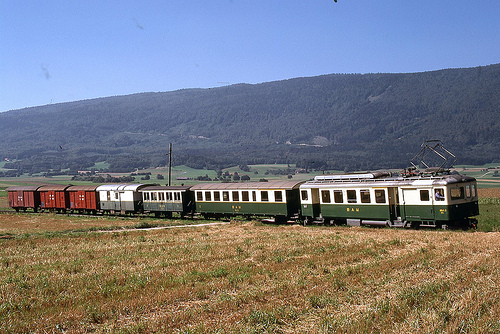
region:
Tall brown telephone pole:
[159, 140, 182, 185]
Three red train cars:
[10, 180, 101, 214]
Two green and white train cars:
[185, 176, 469, 232]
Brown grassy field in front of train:
[22, 217, 477, 332]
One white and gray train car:
[95, 182, 142, 217]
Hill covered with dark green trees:
[6, 60, 489, 172]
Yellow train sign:
[339, 207, 364, 212]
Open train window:
[443, 185, 466, 200]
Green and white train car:
[139, 185, 186, 215]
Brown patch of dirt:
[73, 162, 151, 179]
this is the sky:
[3, 6, 485, 59]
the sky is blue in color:
[3, 0, 188, 38]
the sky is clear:
[11, 6, 483, 29]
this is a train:
[8, 178, 483, 219]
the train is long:
[11, 177, 481, 217]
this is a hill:
[140, 67, 499, 139]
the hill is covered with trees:
[196, 105, 316, 142]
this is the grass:
[52, 245, 218, 326]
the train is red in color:
[18, 190, 75, 201]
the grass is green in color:
[481, 203, 495, 229]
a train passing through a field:
[6, 177, 478, 235]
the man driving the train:
[433, 188, 444, 200]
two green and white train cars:
[188, 170, 480, 232]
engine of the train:
[298, 167, 482, 233]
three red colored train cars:
[7, 180, 97, 214]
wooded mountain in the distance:
[0, 60, 496, 165]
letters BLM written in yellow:
[341, 202, 363, 212]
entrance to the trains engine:
[386, 183, 404, 228]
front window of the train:
[446, 182, 476, 202]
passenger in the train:
[222, 192, 227, 199]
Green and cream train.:
[286, 176, 495, 231]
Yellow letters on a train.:
[332, 201, 363, 222]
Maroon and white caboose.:
[0, 132, 112, 212]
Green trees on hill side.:
[162, 60, 407, 148]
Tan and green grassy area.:
[112, 242, 294, 332]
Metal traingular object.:
[373, 125, 483, 185]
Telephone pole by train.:
[151, 121, 198, 222]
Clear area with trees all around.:
[64, 136, 153, 182]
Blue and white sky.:
[23, 45, 127, 92]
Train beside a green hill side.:
[19, 102, 462, 323]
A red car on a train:
[6, 179, 52, 220]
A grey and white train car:
[94, 181, 139, 225]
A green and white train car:
[190, 178, 301, 241]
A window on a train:
[271, 184, 291, 208]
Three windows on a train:
[343, 187, 389, 212]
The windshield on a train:
[442, 188, 479, 208]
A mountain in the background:
[99, 73, 400, 150]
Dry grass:
[62, 231, 251, 299]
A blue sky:
[220, 21, 378, 64]